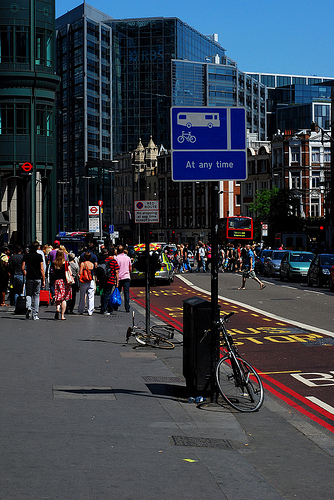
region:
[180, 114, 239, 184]
blue and white sign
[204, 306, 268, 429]
bike is under sign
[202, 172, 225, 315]
sign on black pole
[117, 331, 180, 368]
bike is on ground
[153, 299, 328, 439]
red stripe on road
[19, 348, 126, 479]
road is dark grey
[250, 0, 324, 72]
sky is blue and clear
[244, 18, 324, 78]
no clouds in sky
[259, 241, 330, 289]
cars parked on side of road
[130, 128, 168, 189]
two lights on black pole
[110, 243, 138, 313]
Woman wearing a pink shirt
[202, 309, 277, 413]
Bike leaning against pole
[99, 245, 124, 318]
Man wearing a red shirt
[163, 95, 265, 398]
Blue sign on pole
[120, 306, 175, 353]
Bike laying on the ground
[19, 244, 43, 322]
Man wearing a black shirt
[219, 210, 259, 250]
Red bus on the street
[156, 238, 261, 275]
Crowd of people in the street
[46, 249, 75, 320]
Woman wearing a red skirt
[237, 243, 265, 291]
Man wearing a blue shirt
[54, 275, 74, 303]
Woman wearing a skirt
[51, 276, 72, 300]
Woman is wearing a skirt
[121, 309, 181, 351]
Bicycle on the ground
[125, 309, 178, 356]
Bicycle is on the ground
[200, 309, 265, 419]
Bicycle leaning against a pole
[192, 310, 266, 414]
Bicycle is leaning against a pole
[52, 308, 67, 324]
Woman wearing shoes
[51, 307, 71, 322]
Woman is wearing shoes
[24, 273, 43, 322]
Man wearing pants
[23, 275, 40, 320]
Man is wearing pants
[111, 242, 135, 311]
person wearing a pink shirt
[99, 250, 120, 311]
person wearing a stripped shirt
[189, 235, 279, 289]
people crossing the street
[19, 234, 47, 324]
person wearing a light blue jeans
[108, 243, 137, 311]
person wearing dark blue jeans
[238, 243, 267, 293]
person is wearing blue shirt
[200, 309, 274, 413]
bike parked on a street pole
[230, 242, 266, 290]
person wearing shorts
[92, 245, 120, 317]
person carrying a back pack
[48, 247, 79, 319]
person wearing a long blouse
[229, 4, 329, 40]
clear blue sky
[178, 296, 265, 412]
bike parked near sign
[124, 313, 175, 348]
bike parked near smaller sign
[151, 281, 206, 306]
strip for bus and car parking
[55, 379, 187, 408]
shadow of the sign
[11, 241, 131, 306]
crowd of people carrying luggage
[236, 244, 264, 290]
man crossing the street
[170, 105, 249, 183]
sign saying buses and bikes can park at any time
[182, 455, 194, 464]
piece of litter on the ground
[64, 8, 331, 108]
collection of buildings. must be a city